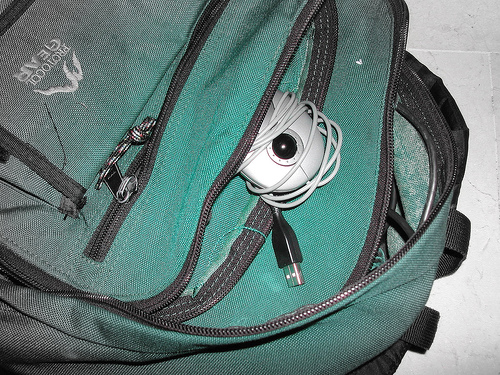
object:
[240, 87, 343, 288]
mouse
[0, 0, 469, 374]
backpack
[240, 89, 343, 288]
cord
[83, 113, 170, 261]
zipper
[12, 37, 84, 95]
emblem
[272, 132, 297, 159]
ball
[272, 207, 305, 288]
usb connector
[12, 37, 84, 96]
protocol gear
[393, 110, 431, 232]
dirt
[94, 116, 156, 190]
rope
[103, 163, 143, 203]
zipper handle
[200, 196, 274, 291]
stitching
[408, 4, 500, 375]
ground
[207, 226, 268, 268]
string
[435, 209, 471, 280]
strap